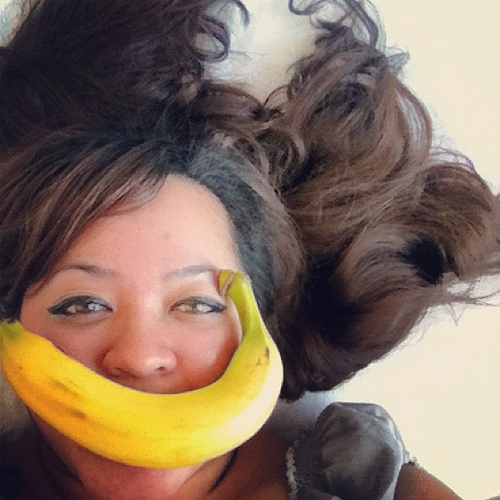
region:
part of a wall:
[263, 31, 280, 67]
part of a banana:
[207, 432, 228, 454]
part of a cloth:
[337, 420, 369, 459]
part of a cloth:
[331, 428, 349, 450]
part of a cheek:
[186, 333, 214, 374]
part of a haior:
[331, 357, 361, 386]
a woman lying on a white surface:
[1, 0, 495, 496]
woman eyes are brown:
[39, 276, 236, 333]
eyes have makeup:
[43, 285, 233, 325]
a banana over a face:
[1, 158, 291, 492]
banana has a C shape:
[1, 249, 293, 474]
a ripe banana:
[0, 259, 297, 481]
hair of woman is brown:
[0, 3, 493, 496]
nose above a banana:
[100, 301, 178, 442]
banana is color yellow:
[6, 252, 287, 478]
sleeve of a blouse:
[264, 388, 430, 498]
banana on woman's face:
[2, 275, 281, 459]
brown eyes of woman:
[44, 278, 220, 325]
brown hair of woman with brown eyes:
[5, 15, 485, 346]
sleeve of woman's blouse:
[280, 400, 408, 495]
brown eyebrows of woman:
[43, 247, 230, 287]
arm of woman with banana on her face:
[394, 450, 464, 499]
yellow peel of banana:
[0, 268, 285, 460]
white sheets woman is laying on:
[6, 8, 493, 499]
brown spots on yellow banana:
[34, 360, 94, 423]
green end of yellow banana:
[1, 315, 26, 340]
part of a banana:
[274, 401, 282, 411]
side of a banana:
[71, 408, 101, 435]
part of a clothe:
[373, 452, 405, 471]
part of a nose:
[149, 344, 164, 356]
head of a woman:
[151, 238, 200, 277]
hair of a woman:
[347, 288, 377, 320]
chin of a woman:
[119, 473, 143, 487]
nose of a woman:
[160, 362, 182, 379]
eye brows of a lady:
[181, 258, 186, 273]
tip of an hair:
[428, 273, 448, 302]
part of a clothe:
[330, 468, 341, 483]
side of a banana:
[147, 421, 164, 446]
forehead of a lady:
[128, 225, 161, 265]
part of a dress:
[326, 457, 343, 494]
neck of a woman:
[192, 476, 202, 484]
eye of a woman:
[188, 303, 215, 324]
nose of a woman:
[131, 339, 156, 359]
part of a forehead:
[149, 228, 154, 268]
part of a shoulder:
[267, 465, 274, 475]